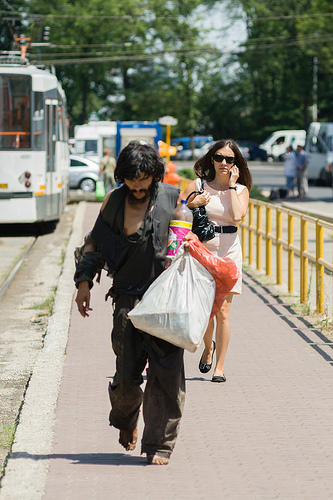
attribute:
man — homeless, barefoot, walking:
[73, 142, 200, 459]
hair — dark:
[114, 141, 165, 187]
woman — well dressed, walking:
[182, 135, 254, 387]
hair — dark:
[192, 134, 252, 191]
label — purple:
[168, 224, 192, 255]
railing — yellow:
[240, 191, 330, 326]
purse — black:
[185, 188, 214, 242]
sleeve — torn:
[73, 183, 120, 287]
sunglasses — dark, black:
[210, 151, 237, 164]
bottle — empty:
[161, 196, 194, 264]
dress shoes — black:
[196, 337, 228, 384]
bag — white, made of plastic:
[124, 241, 220, 355]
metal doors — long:
[42, 95, 61, 221]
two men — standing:
[281, 142, 310, 193]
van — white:
[261, 124, 307, 157]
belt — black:
[210, 222, 239, 238]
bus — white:
[1, 62, 71, 232]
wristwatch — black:
[227, 183, 239, 193]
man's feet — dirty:
[114, 424, 171, 469]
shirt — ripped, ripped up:
[70, 184, 191, 288]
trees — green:
[0, 1, 330, 149]